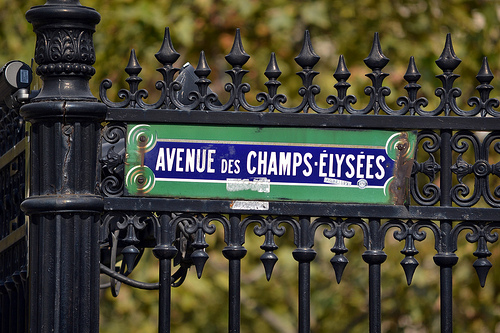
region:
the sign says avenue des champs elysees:
[146, 130, 376, 191]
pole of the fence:
[24, 56, 101, 331]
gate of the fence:
[174, 220, 386, 326]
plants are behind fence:
[184, 0, 356, 47]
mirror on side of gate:
[2, 53, 35, 103]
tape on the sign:
[212, 172, 268, 198]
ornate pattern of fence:
[410, 122, 470, 211]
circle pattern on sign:
[125, 121, 159, 159]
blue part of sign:
[223, 146, 236, 156]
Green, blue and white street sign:
[125, 125, 417, 206]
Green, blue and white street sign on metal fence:
[125, 125, 414, 206]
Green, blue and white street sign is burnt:
[125, 124, 414, 204]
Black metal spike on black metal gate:
[122, 48, 146, 83]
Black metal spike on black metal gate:
[152, 25, 179, 63]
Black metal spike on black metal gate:
[192, 48, 212, 78]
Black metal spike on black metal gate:
[223, 25, 250, 69]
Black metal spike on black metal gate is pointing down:
[122, 246, 142, 274]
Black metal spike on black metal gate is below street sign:
[191, 248, 207, 279]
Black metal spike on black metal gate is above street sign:
[361, 30, 388, 72]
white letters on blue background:
[143, 135, 395, 192]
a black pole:
[20, 1, 111, 331]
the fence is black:
[10, 7, 496, 322]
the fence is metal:
[0, 0, 497, 326]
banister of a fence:
[152, 215, 173, 331]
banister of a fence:
[220, 215, 247, 330]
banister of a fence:
[290, 218, 311, 329]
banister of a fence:
[360, 220, 385, 330]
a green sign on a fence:
[116, 115, 421, 215]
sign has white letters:
[117, 120, 421, 210]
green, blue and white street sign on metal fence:
[114, 115, 431, 222]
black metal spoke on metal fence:
[149, 255, 461, 332]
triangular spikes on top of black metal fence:
[138, 19, 493, 90]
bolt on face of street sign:
[129, 127, 154, 147]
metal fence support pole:
[10, 3, 113, 331]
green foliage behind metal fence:
[5, 3, 494, 328]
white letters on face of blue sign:
[155, 145, 388, 190]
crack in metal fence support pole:
[51, 92, 83, 189]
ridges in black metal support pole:
[22, 216, 102, 331]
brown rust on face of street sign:
[388, 143, 411, 200]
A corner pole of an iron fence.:
[21, 3, 109, 331]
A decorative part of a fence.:
[97, 48, 167, 108]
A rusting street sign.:
[125, 123, 418, 202]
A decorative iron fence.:
[96, 25, 493, 331]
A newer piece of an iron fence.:
[0, 56, 33, 102]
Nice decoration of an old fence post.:
[32, 28, 102, 77]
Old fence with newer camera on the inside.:
[96, 63, 223, 300]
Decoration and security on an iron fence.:
[100, 28, 499, 118]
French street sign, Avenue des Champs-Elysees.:
[153, 147, 385, 183]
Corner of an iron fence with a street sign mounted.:
[0, 7, 497, 329]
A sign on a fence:
[124, 121, 414, 202]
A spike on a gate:
[154, 24, 184, 112]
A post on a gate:
[16, 2, 102, 332]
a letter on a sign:
[149, 142, 166, 172]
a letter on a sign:
[177, 147, 184, 168]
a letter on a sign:
[181, 145, 193, 172]